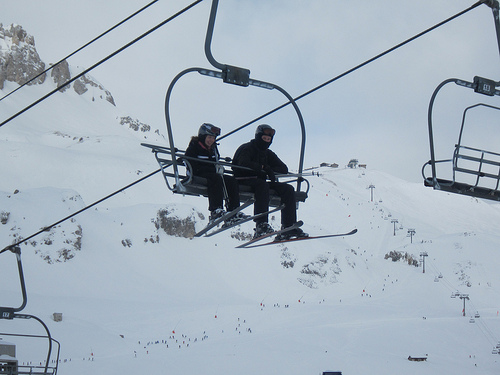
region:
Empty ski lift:
[413, 52, 498, 202]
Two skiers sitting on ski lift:
[129, 12, 373, 282]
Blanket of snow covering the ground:
[6, 43, 494, 371]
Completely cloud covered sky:
[22, 0, 497, 184]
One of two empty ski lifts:
[2, 246, 72, 373]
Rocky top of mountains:
[0, 20, 115, 101]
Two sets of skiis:
[193, 193, 354, 260]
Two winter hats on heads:
[199, 115, 290, 143]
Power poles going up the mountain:
[346, 156, 477, 326]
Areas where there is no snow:
[20, 289, 375, 373]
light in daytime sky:
[3, 5, 497, 166]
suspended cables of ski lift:
[2, 1, 476, 257]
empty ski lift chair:
[421, 75, 497, 196]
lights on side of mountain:
[365, 182, 472, 317]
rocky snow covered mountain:
[1, 25, 406, 371]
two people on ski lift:
[151, 64, 361, 248]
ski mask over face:
[251, 132, 277, 148]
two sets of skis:
[195, 197, 357, 252]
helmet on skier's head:
[195, 122, 222, 144]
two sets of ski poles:
[210, 166, 325, 208]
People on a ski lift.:
[120, 40, 377, 295]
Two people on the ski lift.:
[131, 87, 373, 282]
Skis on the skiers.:
[188, 194, 465, 286]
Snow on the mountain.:
[56, 165, 263, 304]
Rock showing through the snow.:
[141, 199, 238, 262]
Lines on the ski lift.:
[29, 24, 129, 116]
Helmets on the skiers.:
[176, 87, 293, 163]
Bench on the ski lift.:
[137, 127, 342, 236]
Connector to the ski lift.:
[158, 16, 315, 115]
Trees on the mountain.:
[378, 189, 460, 322]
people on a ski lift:
[29, 20, 449, 296]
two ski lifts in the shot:
[33, 29, 493, 234]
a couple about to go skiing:
[167, 89, 344, 270]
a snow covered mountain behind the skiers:
[12, 20, 430, 257]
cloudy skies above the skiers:
[59, 9, 417, 100]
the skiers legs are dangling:
[177, 180, 353, 268]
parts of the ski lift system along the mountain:
[346, 166, 473, 324]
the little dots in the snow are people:
[79, 302, 307, 364]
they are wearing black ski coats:
[186, 112, 299, 209]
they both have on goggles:
[198, 109, 275, 147]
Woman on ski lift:
[181, 119, 228, 209]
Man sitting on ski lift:
[232, 122, 310, 245]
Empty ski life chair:
[421, 58, 498, 211]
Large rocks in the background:
[0, 19, 72, 101]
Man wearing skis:
[229, 222, 361, 255]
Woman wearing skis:
[193, 198, 285, 238]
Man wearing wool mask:
[251, 122, 276, 152]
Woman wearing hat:
[196, 122, 223, 142]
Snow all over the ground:
[0, 66, 497, 374]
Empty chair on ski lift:
[0, 296, 67, 374]